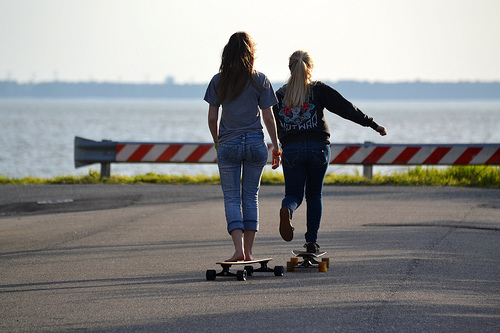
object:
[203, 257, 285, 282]
skateboard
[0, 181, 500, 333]
ground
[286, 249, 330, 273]
skateboard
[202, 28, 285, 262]
woman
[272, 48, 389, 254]
woman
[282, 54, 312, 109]
ponytail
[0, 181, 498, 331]
tar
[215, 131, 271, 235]
jeans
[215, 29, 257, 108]
hair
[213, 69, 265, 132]
back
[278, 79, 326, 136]
back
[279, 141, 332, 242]
jeans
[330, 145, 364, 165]
stripes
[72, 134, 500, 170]
guardrail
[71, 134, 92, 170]
end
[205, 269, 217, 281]
wheel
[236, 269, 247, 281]
wheel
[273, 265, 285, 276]
wheel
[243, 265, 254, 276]
wheel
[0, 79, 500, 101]
land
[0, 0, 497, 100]
horizon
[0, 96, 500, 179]
water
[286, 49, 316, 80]
head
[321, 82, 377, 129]
arm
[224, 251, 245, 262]
feet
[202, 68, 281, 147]
tee shirt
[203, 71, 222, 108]
sleeves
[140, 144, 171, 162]
lines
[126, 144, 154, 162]
line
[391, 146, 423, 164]
line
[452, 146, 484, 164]
line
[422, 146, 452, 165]
line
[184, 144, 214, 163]
line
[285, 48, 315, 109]
hair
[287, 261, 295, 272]
wheel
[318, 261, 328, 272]
wheel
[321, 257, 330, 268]
wheel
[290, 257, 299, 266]
wheel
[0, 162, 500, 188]
grass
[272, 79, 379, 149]
shirt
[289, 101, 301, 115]
face